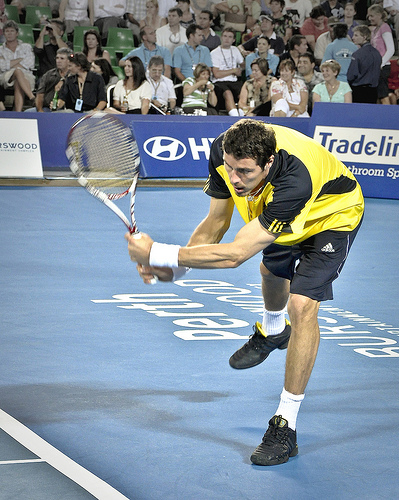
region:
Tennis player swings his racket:
[58, 99, 185, 296]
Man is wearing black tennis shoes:
[246, 417, 313, 475]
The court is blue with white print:
[81, 280, 245, 443]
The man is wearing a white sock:
[269, 380, 308, 448]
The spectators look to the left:
[37, 31, 238, 117]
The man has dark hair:
[219, 120, 284, 208]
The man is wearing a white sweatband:
[149, 234, 187, 280]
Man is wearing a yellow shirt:
[208, 110, 367, 258]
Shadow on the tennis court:
[13, 331, 239, 454]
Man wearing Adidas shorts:
[310, 227, 344, 264]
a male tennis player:
[66, 97, 362, 465]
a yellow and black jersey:
[202, 117, 363, 240]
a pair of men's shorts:
[250, 232, 355, 299]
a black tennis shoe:
[250, 416, 299, 464]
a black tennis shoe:
[226, 321, 296, 367]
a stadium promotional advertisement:
[307, 102, 395, 195]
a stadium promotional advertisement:
[136, 116, 216, 177]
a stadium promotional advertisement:
[0, 117, 41, 172]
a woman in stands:
[107, 53, 154, 113]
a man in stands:
[148, 52, 177, 111]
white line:
[7, 418, 106, 468]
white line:
[70, 455, 90, 468]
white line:
[52, 452, 104, 487]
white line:
[58, 427, 109, 498]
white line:
[52, 471, 81, 483]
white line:
[58, 457, 88, 477]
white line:
[45, 458, 83, 472]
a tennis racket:
[39, 91, 154, 239]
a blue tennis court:
[27, 282, 388, 471]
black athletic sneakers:
[224, 302, 310, 499]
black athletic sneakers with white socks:
[229, 297, 340, 480]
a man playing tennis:
[44, 58, 375, 307]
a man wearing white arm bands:
[121, 87, 289, 288]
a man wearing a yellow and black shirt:
[196, 101, 372, 299]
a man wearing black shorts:
[192, 104, 366, 307]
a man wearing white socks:
[172, 125, 335, 443]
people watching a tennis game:
[20, 6, 397, 123]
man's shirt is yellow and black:
[206, 117, 358, 366]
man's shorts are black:
[242, 190, 369, 333]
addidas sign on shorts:
[310, 241, 345, 262]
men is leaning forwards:
[54, 55, 389, 345]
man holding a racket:
[49, 79, 218, 293]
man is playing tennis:
[42, 49, 341, 314]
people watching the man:
[1, 0, 357, 126]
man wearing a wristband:
[149, 235, 186, 274]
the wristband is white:
[141, 235, 185, 276]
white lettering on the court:
[109, 261, 397, 409]